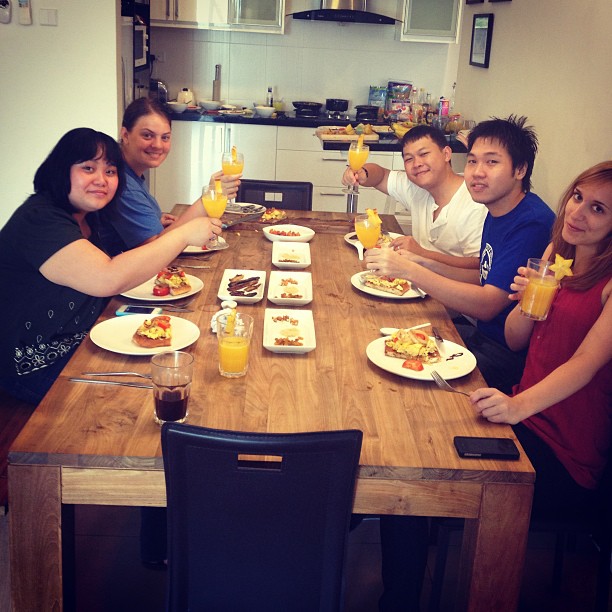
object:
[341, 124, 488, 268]
man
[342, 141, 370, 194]
glass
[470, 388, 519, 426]
hand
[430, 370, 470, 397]
fork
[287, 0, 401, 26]
range hood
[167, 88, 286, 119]
plates/bowls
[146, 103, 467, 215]
counter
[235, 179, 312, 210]
seats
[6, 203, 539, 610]
dining table